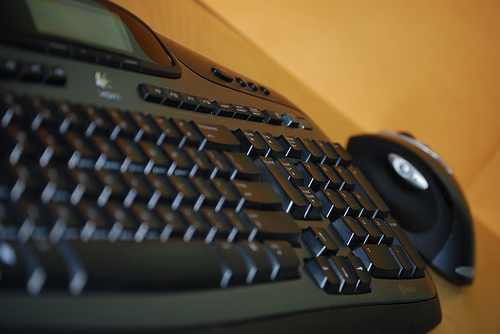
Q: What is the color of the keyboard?
A: Black.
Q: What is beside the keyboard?
A: Mouse.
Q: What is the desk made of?
A: Wood.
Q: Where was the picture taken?
A: At a desk.